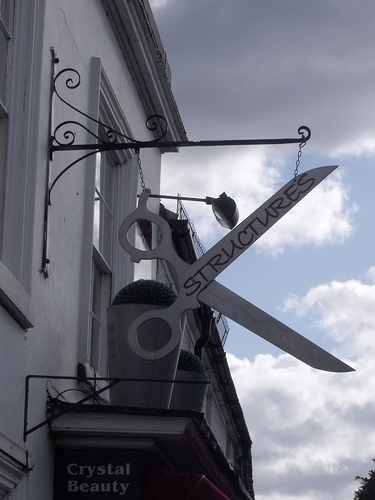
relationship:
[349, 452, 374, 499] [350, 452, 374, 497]
tree with leaves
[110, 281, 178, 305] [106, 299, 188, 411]
plant in pot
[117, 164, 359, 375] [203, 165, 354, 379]
scissors with blades open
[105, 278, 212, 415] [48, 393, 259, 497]
two cups of slushies are on ledge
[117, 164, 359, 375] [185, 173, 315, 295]
scissors have word structures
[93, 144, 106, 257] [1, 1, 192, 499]
light coming out from building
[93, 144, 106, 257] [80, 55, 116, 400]
reflection of clouds are in window